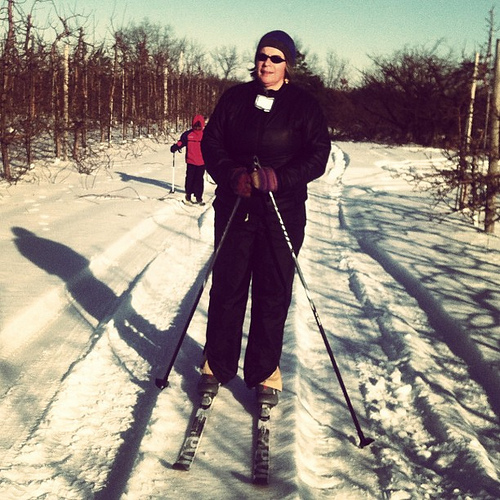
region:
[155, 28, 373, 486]
Women on cross-country skis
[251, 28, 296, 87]
Glasses and winter cap on woman's head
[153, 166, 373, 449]
Ski poles in woman's hands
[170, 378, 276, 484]
Skis on the snow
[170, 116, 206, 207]
Person skiing in opposite direction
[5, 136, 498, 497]
Snow covering the ground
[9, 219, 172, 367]
Woman's shadow on the snow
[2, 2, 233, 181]
Bare trees on left side of trail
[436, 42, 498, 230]
Trees on the side of the trail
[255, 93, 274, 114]
Ski ticket on woman's jacket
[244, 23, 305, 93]
Person wearing blue hat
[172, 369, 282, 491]
Pair of feet and skis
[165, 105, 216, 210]
Skier in red and black snowsuit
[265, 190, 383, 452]
Ski pole in snow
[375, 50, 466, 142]
Clump of trees with no leaves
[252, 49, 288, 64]
Pair of dark glasses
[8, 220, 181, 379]
A shadow of a person in the snow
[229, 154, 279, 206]
Pair of purple gloves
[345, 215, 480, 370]
Tire tracks in the snow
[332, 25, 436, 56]
Grey and cloudy sky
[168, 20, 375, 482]
a person in black on snow skis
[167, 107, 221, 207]
a person in red and black on snow skis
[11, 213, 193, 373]
a shadow on the snow covered ground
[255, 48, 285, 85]
the face of a person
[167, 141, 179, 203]
a hand holding a ski pole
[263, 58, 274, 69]
the nose of a person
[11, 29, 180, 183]
trees lining the side of a snow covered road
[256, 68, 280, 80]
the mouth of a person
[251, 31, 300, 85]
a person wearing sunglasses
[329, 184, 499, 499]
shadows of trees on the snow covered ground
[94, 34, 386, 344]
a skier on the slopes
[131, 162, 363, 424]
this person is holding out their poles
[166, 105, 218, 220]
a skier in the background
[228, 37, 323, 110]
the skier is wearing sunglasses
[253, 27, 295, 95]
the skier has on a hat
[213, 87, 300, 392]
this skier is wearing black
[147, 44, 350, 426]
these skiers are on a trail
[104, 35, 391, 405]
they are skiing through the woods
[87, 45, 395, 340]
two people skiing through a forest area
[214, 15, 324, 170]
this skier looks relaxed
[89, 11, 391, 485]
woman skiing down hill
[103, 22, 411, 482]
woman riding a pair of skis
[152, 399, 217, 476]
long black skis on feet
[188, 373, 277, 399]
grey ski shoes on feet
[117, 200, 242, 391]
black long ski pole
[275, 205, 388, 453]
white and black ski pole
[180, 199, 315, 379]
black ski pants on person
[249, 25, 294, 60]
black beanie on head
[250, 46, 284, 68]
black glasses on face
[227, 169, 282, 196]
red ski gloves on hand